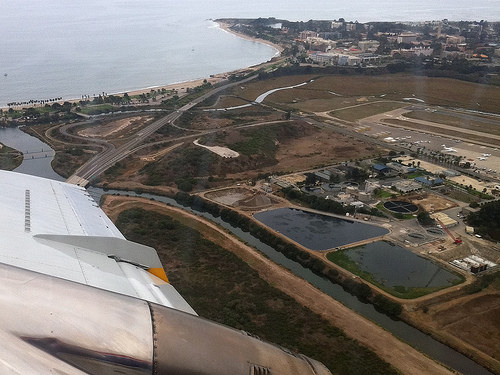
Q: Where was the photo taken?
A: From a plane.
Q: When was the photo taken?
A: Daytime.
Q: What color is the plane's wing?
A: Silver.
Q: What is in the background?
A: A body of water.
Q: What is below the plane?
A: Developed land.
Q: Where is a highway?
A: Running to the coast, left.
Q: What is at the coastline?
A: Beach.